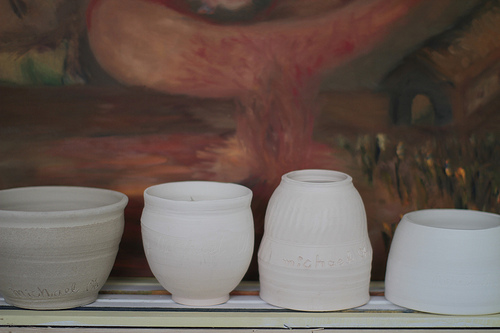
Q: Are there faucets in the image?
A: No, there are no faucets.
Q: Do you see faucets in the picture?
A: No, there are no faucets.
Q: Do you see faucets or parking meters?
A: No, there are no faucets or parking meters.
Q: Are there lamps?
A: No, there are no lamps.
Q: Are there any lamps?
A: No, there are no lamps.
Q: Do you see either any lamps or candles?
A: No, there are no lamps or candles.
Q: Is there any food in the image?
A: No, there is no food.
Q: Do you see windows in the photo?
A: Yes, there is a window.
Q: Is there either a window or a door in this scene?
A: Yes, there is a window.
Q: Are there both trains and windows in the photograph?
A: No, there is a window but no trains.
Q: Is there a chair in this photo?
A: No, there are no chairs.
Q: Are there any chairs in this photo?
A: No, there are no chairs.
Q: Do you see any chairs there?
A: No, there are no chairs.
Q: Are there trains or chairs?
A: No, there are no chairs or trains.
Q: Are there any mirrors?
A: No, there are no mirrors.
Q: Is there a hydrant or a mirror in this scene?
A: No, there are no mirrors or fire hydrants.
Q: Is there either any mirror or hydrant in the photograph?
A: No, there are no mirrors or fire hydrants.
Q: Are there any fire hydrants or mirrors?
A: No, there are no mirrors or fire hydrants.